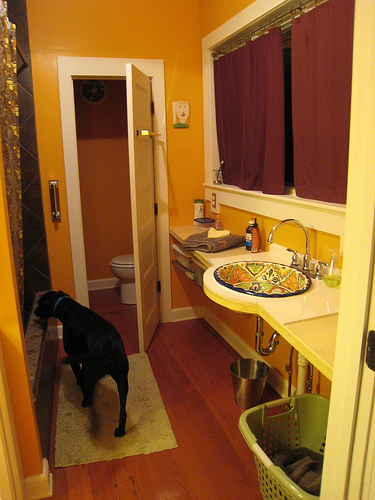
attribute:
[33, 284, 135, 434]
retreiver — labrador, black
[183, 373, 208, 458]
hardwood floor — dark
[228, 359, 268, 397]
waste basket — metal, silver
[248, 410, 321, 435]
basket — green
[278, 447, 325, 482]
laundry — dirty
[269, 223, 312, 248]
sink faucet — silver, stainless steel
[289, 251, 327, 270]
handles — silver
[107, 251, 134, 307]
toilet — white, porcelain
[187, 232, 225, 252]
towel — brown, folded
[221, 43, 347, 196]
curtains — red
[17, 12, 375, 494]
bathroom — painted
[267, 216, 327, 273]
bathroom faucet — chrome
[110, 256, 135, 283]
toilet bowl — porcelain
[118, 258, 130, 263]
toilet seat — plastic, white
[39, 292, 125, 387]
dog — black, large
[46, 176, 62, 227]
handle bar — chrome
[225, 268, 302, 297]
sink — multicolored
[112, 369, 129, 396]
tail — black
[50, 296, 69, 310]
collar — blue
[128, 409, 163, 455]
rug — white, beige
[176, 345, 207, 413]
floor — hardwood, brown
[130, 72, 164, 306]
door — open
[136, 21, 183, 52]
wall — orange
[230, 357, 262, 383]
tin — silver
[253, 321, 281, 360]
pipe — silver, long